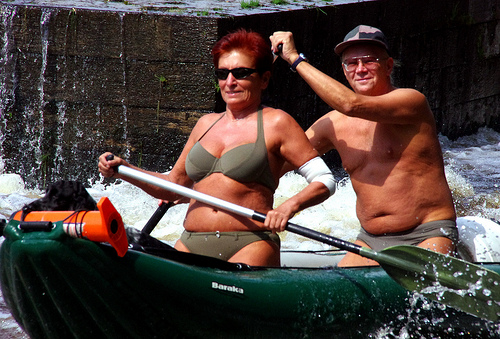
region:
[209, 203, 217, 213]
Belly button of a woman on raft.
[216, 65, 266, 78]
Black sunglasses on mature woman's face.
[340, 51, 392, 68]
Pair of glasses on mature mans face.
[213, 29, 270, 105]
Head of mature woman with red hair.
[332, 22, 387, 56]
Hat on a mans head.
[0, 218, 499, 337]
Green raft in the water.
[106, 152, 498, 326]
Long paddle to row with.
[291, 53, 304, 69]
Watch on mature mans hand.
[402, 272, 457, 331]
Splashes of water.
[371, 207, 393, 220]
Belly button of mature man in raft.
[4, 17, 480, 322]
two people paddle a boat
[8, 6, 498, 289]
a man is woman is swimwear paddle a green canoe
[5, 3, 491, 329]
an older couple are rowing a boat together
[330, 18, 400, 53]
man is wearing a baseball cap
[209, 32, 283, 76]
woman has red hair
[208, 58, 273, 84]
the woman is wearing sunglasses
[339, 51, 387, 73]
man is wearing eyeglasses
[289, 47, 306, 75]
man has wristwatch on his left hand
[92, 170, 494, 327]
woman is holding paddle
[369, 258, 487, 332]
water splashes around the boat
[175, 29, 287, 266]
the woman is old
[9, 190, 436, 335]
the boat is green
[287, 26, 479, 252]
the man has no shirt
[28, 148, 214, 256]
the water is rough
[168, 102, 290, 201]
the bra is green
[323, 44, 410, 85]
the man has glasses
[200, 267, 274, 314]
the word says baraka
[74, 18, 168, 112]
the rock is gray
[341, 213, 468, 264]
the briefs are green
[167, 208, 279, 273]
the swimsuit is green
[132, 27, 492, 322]
man and lady in canoe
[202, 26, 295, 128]
lady wearing sunglasses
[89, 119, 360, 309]
lady holding ore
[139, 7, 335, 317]
lady wearing bikini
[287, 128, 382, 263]
lady wearing elbow band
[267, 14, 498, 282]
man wearing swimming trunks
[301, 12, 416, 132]
man wearing a cap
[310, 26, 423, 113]
man wearing glasses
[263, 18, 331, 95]
man holding ore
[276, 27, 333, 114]
man wearing watch on wrist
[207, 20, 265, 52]
woman's short ginger hair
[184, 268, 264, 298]
white words on green raft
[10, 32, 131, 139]
white rust on black rock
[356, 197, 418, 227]
man's large belly button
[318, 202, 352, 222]
white water rapids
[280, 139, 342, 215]
white band on woman's arm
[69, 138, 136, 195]
oar's black handle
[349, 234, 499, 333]
green oar in rushing water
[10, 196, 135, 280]
orange equipment in front of green raft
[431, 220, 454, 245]
white logo on swimming trunk